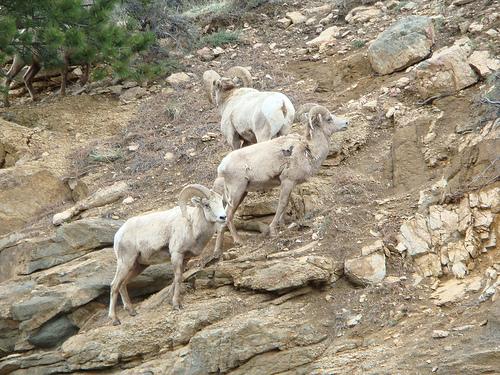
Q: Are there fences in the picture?
A: No, there are no fences.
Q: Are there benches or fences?
A: No, there are no fences or benches.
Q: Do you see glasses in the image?
A: No, there are no glasses.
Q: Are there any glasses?
A: No, there are no glasses.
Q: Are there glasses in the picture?
A: No, there are no glasses.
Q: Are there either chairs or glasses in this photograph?
A: No, there are no glasses or chairs.